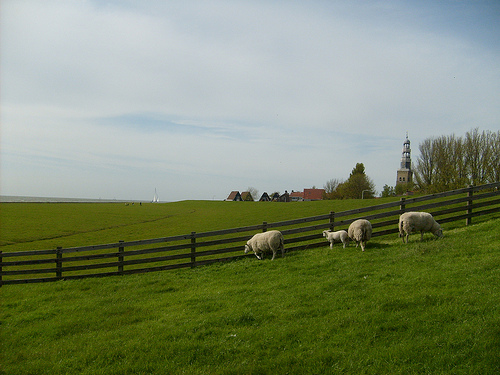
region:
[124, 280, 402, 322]
Grassy green hill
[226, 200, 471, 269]
Sheep on a hill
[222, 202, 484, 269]
sheep eating grass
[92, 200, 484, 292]
Gray fence on a hill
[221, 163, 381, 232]
Houses next to a field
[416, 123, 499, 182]
Trees by a field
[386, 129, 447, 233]
Building by a field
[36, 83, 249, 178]
White cloudy sky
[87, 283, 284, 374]
Long green grass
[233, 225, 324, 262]
A sheep walking on a hill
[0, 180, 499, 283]
A fence made out of wood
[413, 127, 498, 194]
Some green trees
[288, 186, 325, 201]
Buildings with red roofs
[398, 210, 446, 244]
A sheep grazing on grass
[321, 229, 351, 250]
A young sheep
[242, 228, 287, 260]
A sheep grazing next to the fence line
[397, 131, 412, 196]
A tower in the village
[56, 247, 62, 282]
A wooden fence post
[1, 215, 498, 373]
A grassy field for sheep to graze in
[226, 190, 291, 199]
Buildings with very pointy roofs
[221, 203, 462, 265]
FOUR SHEEP BY THE FENCE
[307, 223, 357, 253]
A BABY SHEEP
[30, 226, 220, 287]
A WOODEN FENCE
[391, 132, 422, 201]
A BUILDING IN THE BACKGROUND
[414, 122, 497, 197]
TREES IN THE DISTANCE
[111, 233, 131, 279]
A WOODEN FENCE POLE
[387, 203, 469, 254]
A SHEEP GRAZING ON GRASS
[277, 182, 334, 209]
A BUILDING WITH A RED ROOF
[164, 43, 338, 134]
A CLEAR SKY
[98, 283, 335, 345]
GREEN GRASS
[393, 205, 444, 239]
a white merino sheep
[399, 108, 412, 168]
section of a tall tower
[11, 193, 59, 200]
section of a water body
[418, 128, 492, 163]
section of top of trees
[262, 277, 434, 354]
part of green grass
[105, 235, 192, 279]
section of a wooden fence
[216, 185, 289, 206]
roofs of houses at the far end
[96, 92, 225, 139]
part of the clouded sky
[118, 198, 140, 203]
tiny small animals at the far end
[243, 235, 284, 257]
a white merino sheep next to the fence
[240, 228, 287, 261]
a sheep in the field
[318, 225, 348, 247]
a sheep in the field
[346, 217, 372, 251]
a sheep in the field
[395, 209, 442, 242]
a sheep in the field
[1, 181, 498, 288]
a wooden fence in a field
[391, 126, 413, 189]
a tall building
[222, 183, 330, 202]
some buildings can also be seen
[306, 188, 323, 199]
a building with red roof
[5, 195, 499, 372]
green grass in a field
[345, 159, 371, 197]
a green tree